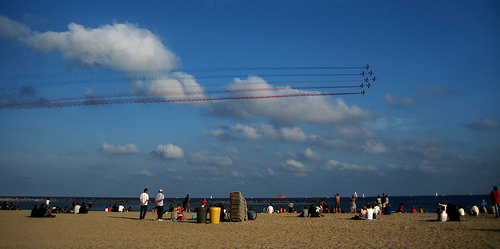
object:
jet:
[365, 64, 370, 69]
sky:
[0, 0, 499, 196]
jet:
[368, 70, 373, 75]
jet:
[362, 67, 375, 96]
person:
[139, 187, 149, 219]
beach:
[0, 206, 500, 249]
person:
[154, 188, 166, 221]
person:
[333, 193, 342, 214]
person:
[349, 192, 358, 214]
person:
[490, 186, 498, 219]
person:
[266, 203, 274, 214]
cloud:
[0, 0, 498, 181]